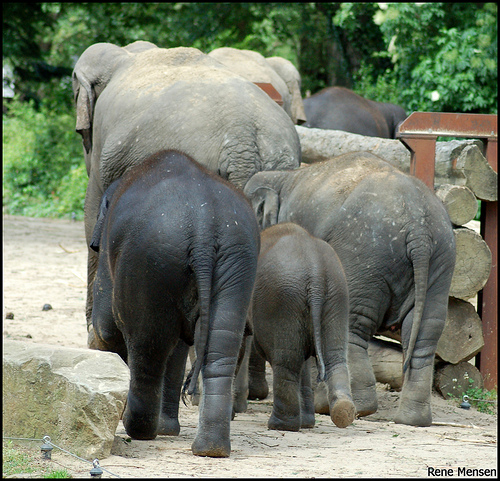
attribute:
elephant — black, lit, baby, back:
[109, 199, 254, 406]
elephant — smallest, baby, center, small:
[279, 253, 388, 411]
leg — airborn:
[315, 359, 389, 445]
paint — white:
[336, 169, 406, 197]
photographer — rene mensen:
[409, 453, 485, 474]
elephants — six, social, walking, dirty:
[133, 25, 404, 425]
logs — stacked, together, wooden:
[434, 149, 494, 388]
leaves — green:
[106, 8, 358, 43]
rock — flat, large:
[33, 342, 141, 399]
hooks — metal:
[31, 431, 99, 480]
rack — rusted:
[421, 109, 493, 153]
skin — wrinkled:
[186, 108, 307, 185]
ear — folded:
[40, 68, 112, 133]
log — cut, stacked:
[428, 138, 486, 186]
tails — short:
[174, 289, 238, 373]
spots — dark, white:
[144, 165, 240, 196]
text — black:
[400, 444, 488, 480]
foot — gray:
[327, 380, 380, 430]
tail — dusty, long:
[379, 247, 452, 389]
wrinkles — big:
[186, 93, 389, 207]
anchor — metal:
[74, 448, 134, 480]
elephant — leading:
[84, 36, 318, 154]